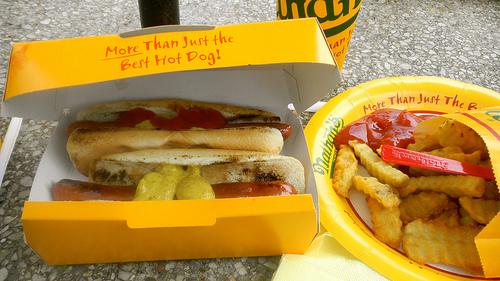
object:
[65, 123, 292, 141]
dogs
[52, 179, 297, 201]
dog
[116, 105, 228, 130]
ketchup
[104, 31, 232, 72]
phrase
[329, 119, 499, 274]
crinkle fries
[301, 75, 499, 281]
paper plate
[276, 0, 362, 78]
drink cup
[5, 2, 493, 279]
tabletop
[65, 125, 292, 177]
bun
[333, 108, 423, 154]
ketchup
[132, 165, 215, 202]
mustard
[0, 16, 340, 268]
box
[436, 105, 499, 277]
bag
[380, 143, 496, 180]
utensil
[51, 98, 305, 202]
food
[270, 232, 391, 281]
napkin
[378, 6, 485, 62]
table